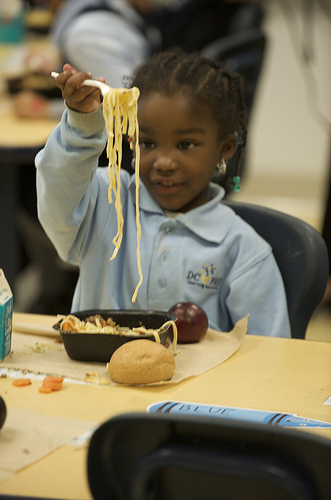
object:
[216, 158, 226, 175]
earring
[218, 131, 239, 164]
ear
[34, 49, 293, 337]
girl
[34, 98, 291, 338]
shirt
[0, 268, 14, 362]
milk carton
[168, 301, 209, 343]
apple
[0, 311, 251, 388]
napkin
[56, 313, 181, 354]
lunch item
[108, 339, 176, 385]
bread roll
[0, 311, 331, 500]
table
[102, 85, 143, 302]
noodles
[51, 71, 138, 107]
fork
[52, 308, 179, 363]
bowl